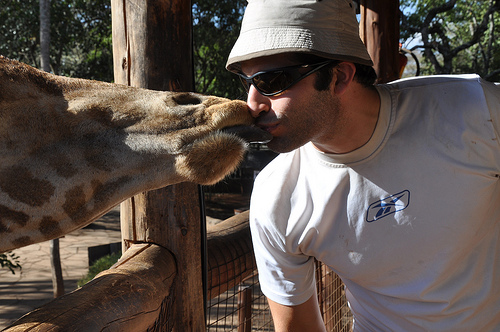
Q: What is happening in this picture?
A: A person is kissing a giraffe.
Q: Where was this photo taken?
A: At an animal exhibit.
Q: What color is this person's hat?
A: White.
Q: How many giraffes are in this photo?
A: One.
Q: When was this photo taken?
A: Outside, during the daytime.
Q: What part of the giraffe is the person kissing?
A: It's tongue.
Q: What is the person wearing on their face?
A: Sunglasses.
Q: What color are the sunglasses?
A: Black.